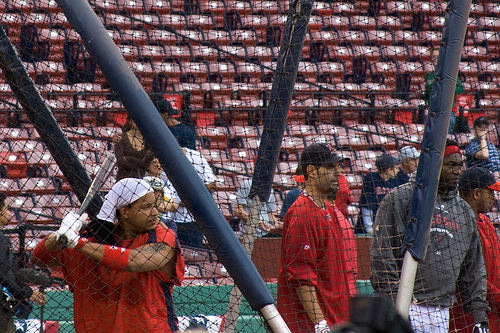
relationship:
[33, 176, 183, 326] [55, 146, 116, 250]
man holding bat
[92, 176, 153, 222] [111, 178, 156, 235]
cloth on head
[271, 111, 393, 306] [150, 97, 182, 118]
man with hat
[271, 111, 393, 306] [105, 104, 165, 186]
man holding woman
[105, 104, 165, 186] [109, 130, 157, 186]
woman in shirt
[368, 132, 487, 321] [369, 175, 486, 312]
man in sweatshirt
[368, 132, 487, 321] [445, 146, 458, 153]
man in headband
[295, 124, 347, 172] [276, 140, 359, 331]
hat on man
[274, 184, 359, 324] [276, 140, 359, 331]
shirt on man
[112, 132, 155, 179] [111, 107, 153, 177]
shirt on woman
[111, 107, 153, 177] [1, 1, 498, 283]
woman in stands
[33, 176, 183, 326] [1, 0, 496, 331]
man in batting cage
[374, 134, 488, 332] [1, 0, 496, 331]
man beside batting cage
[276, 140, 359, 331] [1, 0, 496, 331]
man beside batting cage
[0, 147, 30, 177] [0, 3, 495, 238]
seat in stands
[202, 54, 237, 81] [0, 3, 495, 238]
seat in stands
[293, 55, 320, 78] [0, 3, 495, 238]
seat in stands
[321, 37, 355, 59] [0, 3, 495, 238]
seat in stands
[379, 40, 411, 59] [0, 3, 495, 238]
seat in stands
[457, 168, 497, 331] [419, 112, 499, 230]
man wearing cap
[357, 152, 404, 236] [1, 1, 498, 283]
spectators in stands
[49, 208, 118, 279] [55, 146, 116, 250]
gloves holding bat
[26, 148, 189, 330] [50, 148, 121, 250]
player holding baseball bat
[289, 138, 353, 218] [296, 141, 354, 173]
man wearing cap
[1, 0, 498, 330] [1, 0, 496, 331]
netting around batting cage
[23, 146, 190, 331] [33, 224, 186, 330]
man wearing red shirt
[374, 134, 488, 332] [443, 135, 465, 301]
man wearing band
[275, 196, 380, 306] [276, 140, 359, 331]
shirt on man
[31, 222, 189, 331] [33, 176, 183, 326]
shirt on man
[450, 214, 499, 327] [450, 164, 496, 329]
shirt on man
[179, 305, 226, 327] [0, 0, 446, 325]
flag bunting draping fence